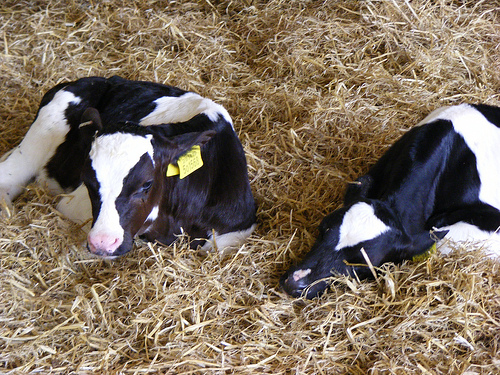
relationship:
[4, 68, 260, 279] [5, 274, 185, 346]
calf in straw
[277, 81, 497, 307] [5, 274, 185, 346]
calf in straw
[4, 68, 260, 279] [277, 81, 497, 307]
calf laying with calf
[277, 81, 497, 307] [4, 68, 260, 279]
calf laying with calf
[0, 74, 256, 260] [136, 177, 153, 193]
calf has eye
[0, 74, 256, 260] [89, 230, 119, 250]
calf has nose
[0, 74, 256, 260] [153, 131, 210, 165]
calf has ear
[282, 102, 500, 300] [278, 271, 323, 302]
calf has nose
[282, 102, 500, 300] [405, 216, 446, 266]
calf has ear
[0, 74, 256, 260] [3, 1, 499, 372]
calf on hay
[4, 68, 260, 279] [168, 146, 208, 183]
calf with tag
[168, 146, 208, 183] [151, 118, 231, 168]
tag in ear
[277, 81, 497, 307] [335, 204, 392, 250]
calf with diamond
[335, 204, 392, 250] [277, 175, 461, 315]
diamond on head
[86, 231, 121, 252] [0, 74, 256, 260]
nose on calf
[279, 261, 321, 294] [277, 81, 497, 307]
nose on calf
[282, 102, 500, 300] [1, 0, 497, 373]
calf in straw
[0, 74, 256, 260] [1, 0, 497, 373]
calf on straw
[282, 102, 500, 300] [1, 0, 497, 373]
calf on straw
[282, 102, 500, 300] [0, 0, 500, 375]
calf on ground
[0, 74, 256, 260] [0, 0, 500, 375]
calf on ground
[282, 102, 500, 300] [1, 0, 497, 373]
calf sleeping on straw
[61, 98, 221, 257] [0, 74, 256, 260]
head on calf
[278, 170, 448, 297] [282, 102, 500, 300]
head on calf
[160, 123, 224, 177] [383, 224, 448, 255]
ear on ear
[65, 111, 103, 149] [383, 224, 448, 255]
ear on ear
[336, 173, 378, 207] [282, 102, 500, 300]
ear on calf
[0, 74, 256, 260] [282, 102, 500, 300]
calf on calf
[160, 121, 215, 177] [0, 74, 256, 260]
ear on calf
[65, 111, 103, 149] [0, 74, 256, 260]
ear on calf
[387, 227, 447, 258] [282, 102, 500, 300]
ear on calf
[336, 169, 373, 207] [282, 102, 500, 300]
ear on calf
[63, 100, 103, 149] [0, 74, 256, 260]
ear on calf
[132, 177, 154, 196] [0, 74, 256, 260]
eye on calf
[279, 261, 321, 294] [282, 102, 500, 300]
nose on calf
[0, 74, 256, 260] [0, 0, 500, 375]
calf laying in ground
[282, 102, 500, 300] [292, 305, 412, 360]
calf laying in hay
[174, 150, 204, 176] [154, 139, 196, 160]
paper attached to ear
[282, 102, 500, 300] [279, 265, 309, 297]
calf has a nose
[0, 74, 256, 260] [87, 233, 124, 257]
calf has a nose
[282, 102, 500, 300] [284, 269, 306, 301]
calf has a nose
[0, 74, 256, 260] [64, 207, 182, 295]
calf with nose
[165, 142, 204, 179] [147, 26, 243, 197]
paper in ear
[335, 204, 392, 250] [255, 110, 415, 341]
diamond on head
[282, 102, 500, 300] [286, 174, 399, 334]
calf with nose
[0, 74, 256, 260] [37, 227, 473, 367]
calf on straw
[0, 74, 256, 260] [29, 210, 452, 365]
calf on straw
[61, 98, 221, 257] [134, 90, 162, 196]
head with line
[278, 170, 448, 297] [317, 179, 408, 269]
head with diamond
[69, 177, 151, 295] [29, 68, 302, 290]
nose of cow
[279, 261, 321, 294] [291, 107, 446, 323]
nose in cow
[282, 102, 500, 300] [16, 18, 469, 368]
calf in ground